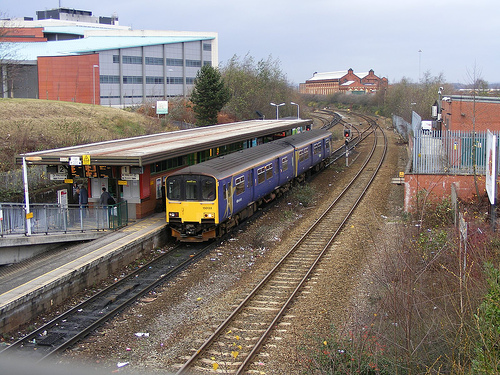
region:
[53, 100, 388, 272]
train at station in rural area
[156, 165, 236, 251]
front of train is yellow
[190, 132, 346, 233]
cars for passengers are blue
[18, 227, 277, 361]
trash and debris near the tracks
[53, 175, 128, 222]
people in the train station walking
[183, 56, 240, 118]
pine tree on nearby hill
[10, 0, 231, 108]
office building in background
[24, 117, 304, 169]
roof over train station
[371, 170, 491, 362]
bushes alongside train tracks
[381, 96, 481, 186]
fenced area near bulding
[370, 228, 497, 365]
The bushes are dead.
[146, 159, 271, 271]
The bus is yellow.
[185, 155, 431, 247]
The train is blue on the side.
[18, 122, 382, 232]
The train station is busy.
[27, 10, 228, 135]
The building has many windows.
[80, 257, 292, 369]
The tracks are black and brown.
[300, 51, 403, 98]
The building has a white roof.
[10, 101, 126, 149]
The bushes are tan.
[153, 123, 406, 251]
The train is short.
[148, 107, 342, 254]
The train is stopped.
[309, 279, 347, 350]
part of a ground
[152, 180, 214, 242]
front of a train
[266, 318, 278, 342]
edge of a train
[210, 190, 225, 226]
edge of a train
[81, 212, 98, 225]
part of a fence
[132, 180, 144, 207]
part of a wall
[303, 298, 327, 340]
part of a ground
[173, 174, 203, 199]
part of a window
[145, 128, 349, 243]
short train on tracks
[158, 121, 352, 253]
train is yellow and blue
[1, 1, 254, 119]
building in the background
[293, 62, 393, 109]
building in the background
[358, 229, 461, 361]
trees have no leaves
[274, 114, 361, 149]
signal lights are on red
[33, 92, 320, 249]
train station is long and narrow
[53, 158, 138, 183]
electronic billboard shows information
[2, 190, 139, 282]
access to station is sloped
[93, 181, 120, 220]
person is carrying a backpack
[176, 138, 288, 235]
this is a train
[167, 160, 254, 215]
the train is parked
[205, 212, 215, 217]
the light is on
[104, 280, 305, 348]
these are the rails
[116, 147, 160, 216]
this is the station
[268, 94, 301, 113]
these are the street lights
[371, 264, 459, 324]
the branches are dry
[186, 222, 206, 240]
the front is metallic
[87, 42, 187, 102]
the building is tall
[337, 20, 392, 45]
the sky is grey in collor